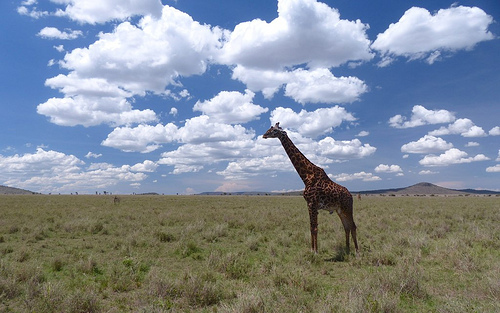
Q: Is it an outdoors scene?
A: Yes, it is outdoors.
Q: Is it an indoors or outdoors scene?
A: It is outdoors.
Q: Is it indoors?
A: No, it is outdoors.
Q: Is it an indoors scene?
A: No, it is outdoors.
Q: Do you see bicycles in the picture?
A: No, there are no bicycles.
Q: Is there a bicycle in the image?
A: No, there are no bicycles.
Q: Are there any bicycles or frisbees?
A: No, there are no bicycles or frisbees.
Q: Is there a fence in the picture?
A: No, there are no fences.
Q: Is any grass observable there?
A: Yes, there is grass.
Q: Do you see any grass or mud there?
A: Yes, there is grass.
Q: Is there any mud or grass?
A: Yes, there is grass.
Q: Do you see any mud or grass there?
A: Yes, there is grass.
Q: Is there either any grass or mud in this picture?
A: Yes, there is grass.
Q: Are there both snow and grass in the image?
A: No, there is grass but no snow.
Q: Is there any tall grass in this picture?
A: Yes, there is tall grass.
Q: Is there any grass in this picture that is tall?
A: Yes, there is grass that is tall.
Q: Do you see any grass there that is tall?
A: Yes, there is grass that is tall.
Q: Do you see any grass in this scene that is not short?
A: Yes, there is tall grass.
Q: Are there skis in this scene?
A: No, there are no skis.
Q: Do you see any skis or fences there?
A: No, there are no skis or fences.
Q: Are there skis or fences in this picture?
A: No, there are no skis or fences.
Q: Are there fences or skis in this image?
A: No, there are no skis or fences.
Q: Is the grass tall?
A: Yes, the grass is tall.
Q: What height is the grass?
A: The grass is tall.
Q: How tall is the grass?
A: The grass is tall.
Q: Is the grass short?
A: No, the grass is tall.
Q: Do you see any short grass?
A: No, there is grass but it is tall.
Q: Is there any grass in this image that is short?
A: No, there is grass but it is tall.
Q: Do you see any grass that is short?
A: No, there is grass but it is tall.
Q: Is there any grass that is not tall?
A: No, there is grass but it is tall.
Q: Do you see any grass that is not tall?
A: No, there is grass but it is tall.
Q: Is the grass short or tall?
A: The grass is tall.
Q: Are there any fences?
A: No, there are no fences.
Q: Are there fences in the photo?
A: No, there are no fences.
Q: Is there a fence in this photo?
A: No, there are no fences.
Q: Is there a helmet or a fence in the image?
A: No, there are no fences or helmets.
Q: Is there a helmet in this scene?
A: No, there are no helmets.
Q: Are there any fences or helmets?
A: No, there are no helmets or fences.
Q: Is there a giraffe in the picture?
A: Yes, there is a giraffe.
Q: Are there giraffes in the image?
A: Yes, there is a giraffe.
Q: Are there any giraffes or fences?
A: Yes, there is a giraffe.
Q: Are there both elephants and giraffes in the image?
A: No, there is a giraffe but no elephants.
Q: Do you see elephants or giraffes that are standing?
A: Yes, the giraffe is standing.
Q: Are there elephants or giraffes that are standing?
A: Yes, the giraffe is standing.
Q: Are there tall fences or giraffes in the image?
A: Yes, there is a tall giraffe.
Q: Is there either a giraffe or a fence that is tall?
A: Yes, the giraffe is tall.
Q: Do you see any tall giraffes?
A: Yes, there is a tall giraffe.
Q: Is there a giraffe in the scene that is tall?
A: Yes, there is a giraffe that is tall.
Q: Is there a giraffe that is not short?
A: Yes, there is a tall giraffe.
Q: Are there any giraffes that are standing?
A: Yes, there is a giraffe that is standing.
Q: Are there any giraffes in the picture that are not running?
A: Yes, there is a giraffe that is standing.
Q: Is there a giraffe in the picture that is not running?
A: Yes, there is a giraffe that is standing.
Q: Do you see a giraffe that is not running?
A: Yes, there is a giraffe that is standing .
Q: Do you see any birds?
A: No, there are no birds.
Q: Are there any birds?
A: No, there are no birds.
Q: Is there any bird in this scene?
A: No, there are no birds.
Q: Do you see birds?
A: No, there are no birds.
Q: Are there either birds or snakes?
A: No, there are no birds or snakes.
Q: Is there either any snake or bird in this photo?
A: No, there are no birds or snakes.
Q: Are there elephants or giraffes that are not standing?
A: No, there is a giraffe but it is standing.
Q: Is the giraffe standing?
A: Yes, the giraffe is standing.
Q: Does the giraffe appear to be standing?
A: Yes, the giraffe is standing.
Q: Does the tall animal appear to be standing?
A: Yes, the giraffe is standing.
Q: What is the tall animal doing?
A: The giraffe is standing.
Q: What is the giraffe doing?
A: The giraffe is standing.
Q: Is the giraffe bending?
A: No, the giraffe is standing.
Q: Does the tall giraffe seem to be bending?
A: No, the giraffe is standing.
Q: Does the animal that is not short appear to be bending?
A: No, the giraffe is standing.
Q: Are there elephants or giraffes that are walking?
A: No, there is a giraffe but it is standing.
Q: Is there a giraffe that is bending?
A: No, there is a giraffe but it is standing.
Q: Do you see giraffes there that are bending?
A: No, there is a giraffe but it is standing.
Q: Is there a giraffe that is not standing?
A: No, there is a giraffe but it is standing.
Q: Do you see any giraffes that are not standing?
A: No, there is a giraffe but it is standing.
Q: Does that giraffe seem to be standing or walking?
A: The giraffe is standing.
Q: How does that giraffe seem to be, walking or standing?
A: The giraffe is standing.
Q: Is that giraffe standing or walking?
A: The giraffe is standing.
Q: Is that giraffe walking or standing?
A: The giraffe is standing.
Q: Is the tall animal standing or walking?
A: The giraffe is standing.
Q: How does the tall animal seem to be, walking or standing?
A: The giraffe is standing.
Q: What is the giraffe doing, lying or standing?
A: The giraffe is standing.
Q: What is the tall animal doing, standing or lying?
A: The giraffe is standing.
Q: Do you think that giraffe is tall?
A: Yes, the giraffe is tall.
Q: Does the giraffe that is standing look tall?
A: Yes, the giraffe is tall.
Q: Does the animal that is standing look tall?
A: Yes, the giraffe is tall.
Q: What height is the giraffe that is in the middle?
A: The giraffe is tall.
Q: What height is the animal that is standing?
A: The giraffe is tall.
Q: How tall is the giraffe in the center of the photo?
A: The giraffe is tall.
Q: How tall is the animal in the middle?
A: The giraffe is tall.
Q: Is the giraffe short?
A: No, the giraffe is tall.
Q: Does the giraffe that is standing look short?
A: No, the giraffe is tall.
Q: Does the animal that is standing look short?
A: No, the giraffe is tall.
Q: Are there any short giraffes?
A: No, there is a giraffe but it is tall.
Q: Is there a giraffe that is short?
A: No, there is a giraffe but it is tall.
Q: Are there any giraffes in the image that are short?
A: No, there is a giraffe but it is tall.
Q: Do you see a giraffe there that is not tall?
A: No, there is a giraffe but it is tall.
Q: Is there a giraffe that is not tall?
A: No, there is a giraffe but it is tall.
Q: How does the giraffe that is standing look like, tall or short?
A: The giraffe is tall.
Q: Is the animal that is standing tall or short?
A: The giraffe is tall.